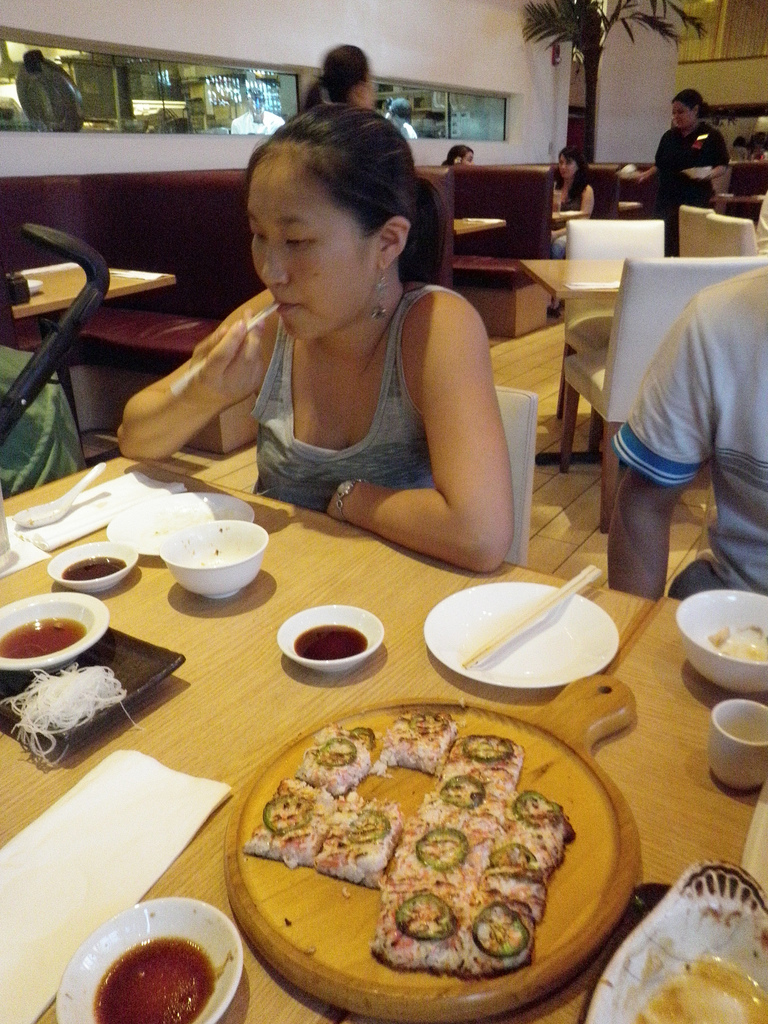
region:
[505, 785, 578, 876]
pizza on a plate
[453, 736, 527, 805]
pizza on a plage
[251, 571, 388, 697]
bowl on a table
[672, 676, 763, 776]
cup on a table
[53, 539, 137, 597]
bowl on a table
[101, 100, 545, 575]
Woman eating with chopsticks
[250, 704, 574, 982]
Fish or sushi on a tray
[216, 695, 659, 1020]
A round wooden tray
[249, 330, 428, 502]
A sleeveless gray shirt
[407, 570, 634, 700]
A white bowl with chopsticks on it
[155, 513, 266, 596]
A small round empty white bowl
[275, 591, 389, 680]
A very small bowl with brown sauce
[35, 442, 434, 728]
A light brown wooden table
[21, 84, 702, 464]
Booths behind the lady with chopsticks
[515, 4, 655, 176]
A tall green plant in the background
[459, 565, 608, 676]
chopsticks on small plate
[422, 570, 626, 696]
white plate on table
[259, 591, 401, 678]
small white bowl on table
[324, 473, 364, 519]
watch on woman's wrist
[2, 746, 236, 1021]
white napkin on table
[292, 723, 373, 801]
sushi on the wooden pan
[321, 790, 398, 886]
sushi on the wooden pan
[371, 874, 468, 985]
sushi on the wooden pan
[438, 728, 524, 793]
sushi on the wooden pan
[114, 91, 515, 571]
woman using pair of chopsticks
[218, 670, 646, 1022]
partially eaten pizza on wood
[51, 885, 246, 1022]
red sauce in white bowl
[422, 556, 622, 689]
wood chopsticks on white plate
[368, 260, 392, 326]
earring in the woman's ear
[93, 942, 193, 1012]
red sauce in the bowl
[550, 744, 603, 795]
tray that is holding the food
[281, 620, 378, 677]
brown sauce in the bowl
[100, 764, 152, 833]
napkin on the table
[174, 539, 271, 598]
empty bowl on the table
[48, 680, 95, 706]
rice noodle on the tray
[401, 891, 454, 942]
jalepeno on the food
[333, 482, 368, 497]
watch on the woman's wrist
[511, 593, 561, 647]
chopsticks on the plate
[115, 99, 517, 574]
woman eating with set of chopsticks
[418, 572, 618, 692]
white plate with set of chopsticks on top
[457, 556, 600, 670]
set of chopsticks resting on white plate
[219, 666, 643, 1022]
wooden serving board with food on top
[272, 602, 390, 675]
one of several bowls of dipping sauce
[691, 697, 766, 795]
cup for drinking tea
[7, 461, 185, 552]
napkin with soup spoon on top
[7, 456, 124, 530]
Asian-style spoon used for soup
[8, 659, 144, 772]
small batch of glass noodles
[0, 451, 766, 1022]
dining table with woodgrain top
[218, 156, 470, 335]
the head of a woman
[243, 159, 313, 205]
the forehead of a woman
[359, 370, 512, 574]
the left arm of a woman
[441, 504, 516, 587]
the elbow of a woman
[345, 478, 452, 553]
the forearm of a woman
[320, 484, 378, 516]
the watch of a woman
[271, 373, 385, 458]
the chest of a woman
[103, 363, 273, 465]
the arm of a woman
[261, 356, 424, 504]
the tanktop of a woman